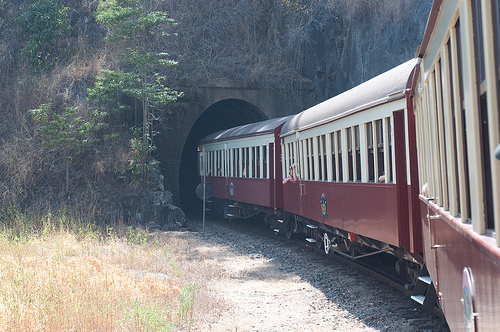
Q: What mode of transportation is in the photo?
A: Train.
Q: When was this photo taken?
A: Daytime.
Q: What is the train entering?
A: Tunnel.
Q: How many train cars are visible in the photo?
A: Three.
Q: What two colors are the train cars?
A: Red, White.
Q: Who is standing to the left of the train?
A: No one.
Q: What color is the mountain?
A: Grey.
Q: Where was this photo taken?
A: On the train tracks.